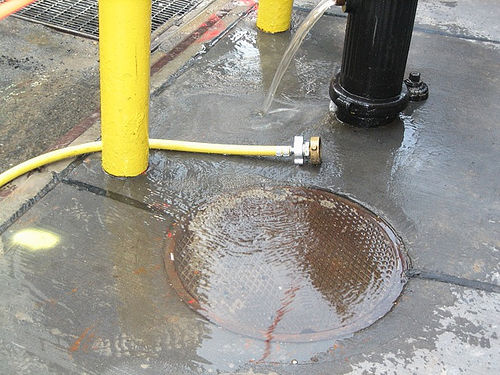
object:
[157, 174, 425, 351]
manhole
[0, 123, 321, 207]
hose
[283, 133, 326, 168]
connector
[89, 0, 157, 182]
pole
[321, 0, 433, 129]
hydrant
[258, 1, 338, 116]
water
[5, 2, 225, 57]
grate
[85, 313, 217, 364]
footprint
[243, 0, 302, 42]
pole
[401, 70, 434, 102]
bolt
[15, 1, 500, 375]
sidewalk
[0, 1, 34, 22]
wire